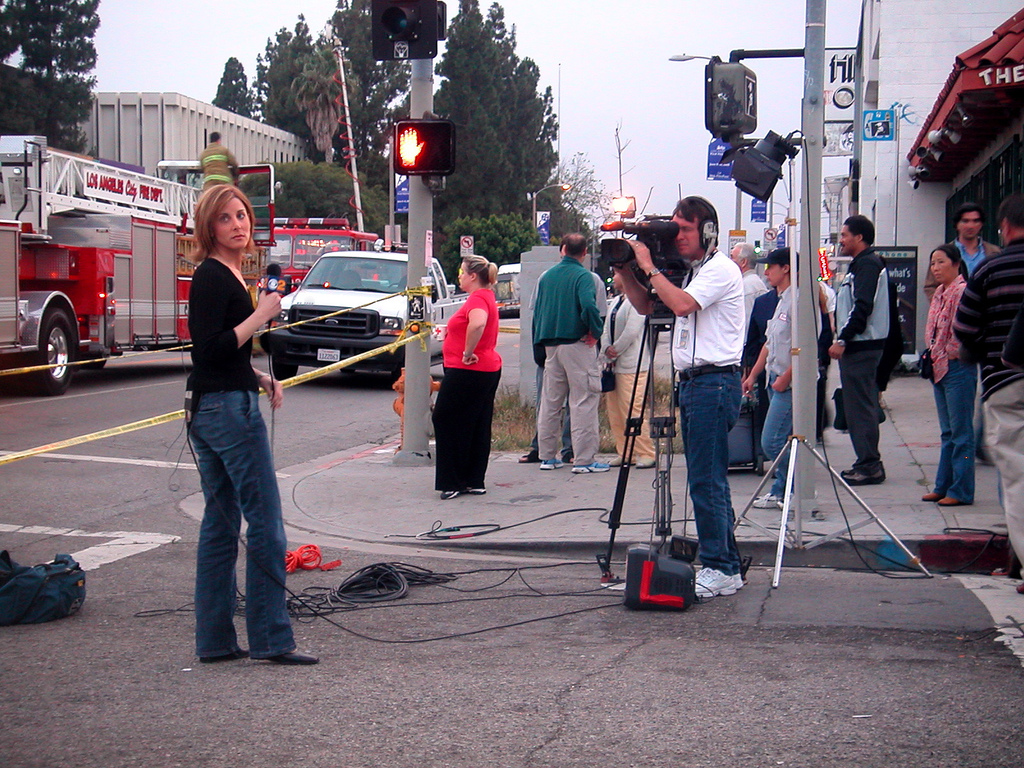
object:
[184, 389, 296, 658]
pants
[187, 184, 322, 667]
lady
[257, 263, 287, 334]
microphone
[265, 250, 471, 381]
truck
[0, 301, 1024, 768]
street